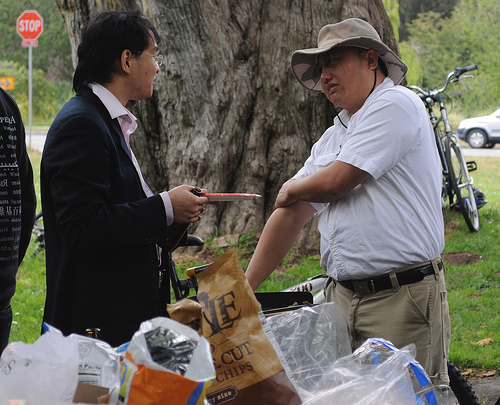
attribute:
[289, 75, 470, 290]
shirt — white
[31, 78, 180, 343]
jacket — black, suit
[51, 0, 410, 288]
trunk — very large, light brown, grey, tree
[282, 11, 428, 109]
hat — camouflaged, sun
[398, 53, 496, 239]
bicycle — silver, green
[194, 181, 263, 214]
plate — disposable, red, paper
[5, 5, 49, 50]
sign — stop, octagonal, red, white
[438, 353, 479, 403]
tire — black, rubber, part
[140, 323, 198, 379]
inside — silver, foiled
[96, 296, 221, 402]
bag — chip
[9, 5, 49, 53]
sign — stop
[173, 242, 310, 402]
bag — chips, brown, kettle, cooked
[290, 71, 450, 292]
shirt — white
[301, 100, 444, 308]
shirt — white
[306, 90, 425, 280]
shirt — white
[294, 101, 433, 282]
shirt — white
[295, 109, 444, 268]
shirt — white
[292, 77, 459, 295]
shirt — white